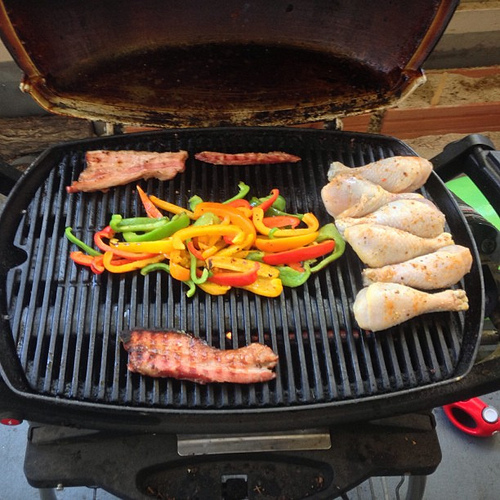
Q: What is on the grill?
A: Food.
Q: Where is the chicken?
A: On the right.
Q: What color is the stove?
A: Black.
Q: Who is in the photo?
A: No one.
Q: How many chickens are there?
A: Six.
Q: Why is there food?
A: To eat.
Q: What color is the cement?
A: Gray.